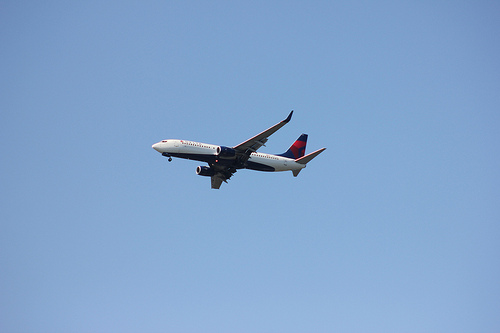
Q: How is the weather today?
A: It is sunny.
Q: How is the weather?
A: It is sunny.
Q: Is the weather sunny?
A: Yes, it is sunny.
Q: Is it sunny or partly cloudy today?
A: It is sunny.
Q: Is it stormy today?
A: No, it is sunny.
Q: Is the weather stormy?
A: No, it is sunny.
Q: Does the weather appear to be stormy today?
A: No, it is sunny.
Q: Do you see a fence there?
A: No, there are no fences.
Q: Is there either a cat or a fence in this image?
A: No, there are no fences or cats.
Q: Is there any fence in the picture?
A: No, there are no fences.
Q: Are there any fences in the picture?
A: No, there are no fences.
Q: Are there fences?
A: No, there are no fences.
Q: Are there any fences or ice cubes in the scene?
A: No, there are no fences or ice cubes.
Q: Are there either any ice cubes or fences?
A: No, there are no fences or ice cubes.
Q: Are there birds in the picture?
A: No, there are no birds.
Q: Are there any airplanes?
A: Yes, there is an airplane.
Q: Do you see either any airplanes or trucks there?
A: Yes, there is an airplane.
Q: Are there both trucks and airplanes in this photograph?
A: No, there is an airplane but no trucks.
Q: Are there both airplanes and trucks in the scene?
A: No, there is an airplane but no trucks.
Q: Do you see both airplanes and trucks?
A: No, there is an airplane but no trucks.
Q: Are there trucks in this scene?
A: No, there are no trucks.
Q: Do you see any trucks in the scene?
A: No, there are no trucks.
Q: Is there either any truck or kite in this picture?
A: No, there are no trucks or kites.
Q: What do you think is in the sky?
A: The plane is in the sky.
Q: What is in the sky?
A: The plane is in the sky.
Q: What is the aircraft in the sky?
A: The aircraft is an airplane.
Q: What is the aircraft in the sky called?
A: The aircraft is an airplane.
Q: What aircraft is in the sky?
A: The aircraft is an airplane.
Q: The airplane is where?
A: The airplane is in the sky.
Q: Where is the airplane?
A: The airplane is in the sky.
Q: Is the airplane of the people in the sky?
A: Yes, the airplane is in the sky.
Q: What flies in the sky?
A: The plane flies in the sky.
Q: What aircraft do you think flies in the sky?
A: The aircraft is an airplane.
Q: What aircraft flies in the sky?
A: The aircraft is an airplane.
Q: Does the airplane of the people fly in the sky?
A: Yes, the plane flies in the sky.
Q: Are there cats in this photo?
A: No, there are no cats.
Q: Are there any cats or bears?
A: No, there are no cats or bears.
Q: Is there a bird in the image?
A: No, there are no birds.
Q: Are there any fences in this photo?
A: No, there are no fences.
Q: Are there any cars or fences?
A: No, there are no fences or cars.